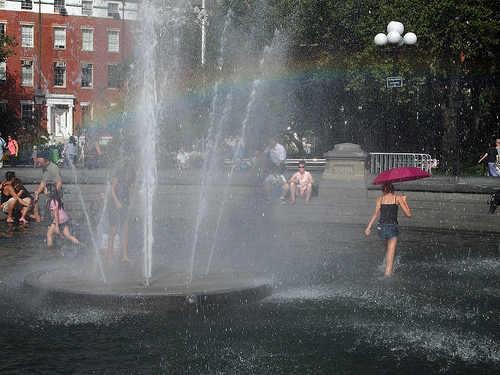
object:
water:
[63, 6, 318, 284]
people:
[0, 170, 31, 226]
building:
[4, 3, 190, 169]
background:
[1, 0, 499, 174]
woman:
[365, 182, 412, 277]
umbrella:
[372, 163, 432, 185]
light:
[373, 19, 420, 137]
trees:
[185, 0, 499, 166]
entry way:
[45, 92, 74, 141]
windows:
[0, 18, 125, 90]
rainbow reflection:
[63, 48, 355, 153]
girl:
[43, 183, 86, 248]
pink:
[47, 198, 69, 224]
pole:
[391, 55, 399, 103]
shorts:
[52, 219, 69, 229]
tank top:
[375, 198, 399, 215]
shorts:
[377, 223, 399, 241]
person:
[104, 164, 137, 264]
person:
[288, 160, 315, 206]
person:
[263, 166, 290, 205]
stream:
[125, 6, 162, 283]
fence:
[372, 166, 431, 185]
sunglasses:
[298, 166, 305, 168]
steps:
[189, 179, 499, 235]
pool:
[0, 228, 500, 375]